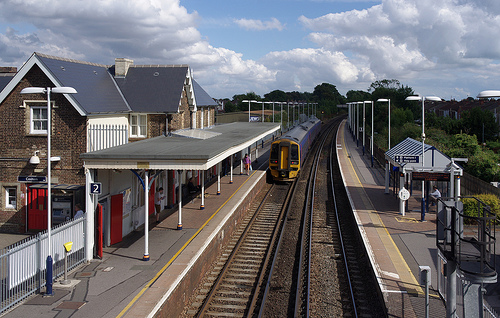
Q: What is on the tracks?
A: A train.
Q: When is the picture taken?
A: Day time.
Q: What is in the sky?
A: Clouds.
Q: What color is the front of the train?
A: Yellow.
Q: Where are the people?
A: On the platform.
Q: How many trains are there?
A: One.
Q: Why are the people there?
A: Waiting for the train.